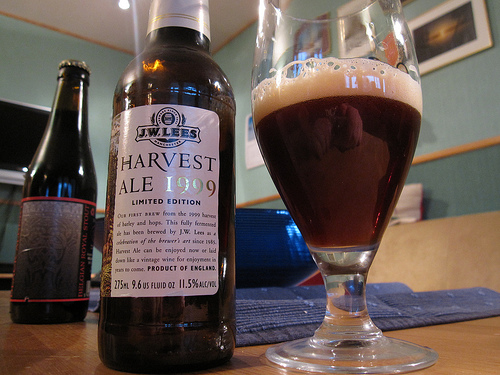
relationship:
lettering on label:
[116, 148, 218, 210] [111, 105, 223, 304]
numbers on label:
[114, 278, 196, 292] [111, 105, 223, 304]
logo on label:
[129, 110, 204, 147] [111, 105, 223, 304]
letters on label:
[72, 202, 95, 300] [10, 193, 98, 303]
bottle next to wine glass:
[101, 2, 243, 367] [248, 1, 446, 375]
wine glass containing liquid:
[248, 1, 446, 375] [257, 97, 417, 241]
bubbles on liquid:
[249, 59, 426, 129] [257, 97, 417, 241]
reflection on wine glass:
[297, 104, 388, 243] [248, 1, 446, 375]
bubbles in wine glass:
[249, 59, 426, 129] [248, 1, 446, 375]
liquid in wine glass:
[257, 97, 417, 241] [248, 1, 446, 375]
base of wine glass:
[276, 328, 436, 375] [248, 1, 446, 375]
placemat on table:
[65, 272, 499, 338] [1, 224, 499, 373]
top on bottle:
[60, 59, 96, 77] [15, 59, 99, 329]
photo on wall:
[406, 1, 492, 69] [199, 3, 498, 225]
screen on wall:
[3, 96, 58, 195] [3, 16, 138, 233]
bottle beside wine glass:
[101, 2, 243, 367] [248, 1, 446, 375]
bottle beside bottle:
[101, 2, 243, 367] [15, 59, 99, 329]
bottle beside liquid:
[101, 2, 243, 367] [257, 97, 417, 241]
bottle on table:
[101, 2, 243, 367] [1, 224, 499, 373]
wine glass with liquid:
[248, 1, 446, 375] [257, 97, 417, 241]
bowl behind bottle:
[75, 202, 323, 292] [101, 2, 243, 367]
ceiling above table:
[3, 3, 261, 69] [1, 224, 499, 373]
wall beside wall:
[199, 3, 498, 225] [3, 16, 138, 233]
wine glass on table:
[248, 1, 446, 375] [1, 224, 499, 373]